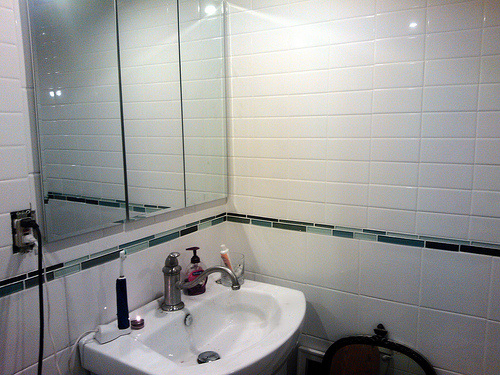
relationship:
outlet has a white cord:
[14, 232, 43, 247] [3, 207, 77, 366]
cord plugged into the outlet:
[3, 207, 77, 366] [14, 232, 43, 247]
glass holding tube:
[24, 81, 314, 216] [216, 244, 236, 283]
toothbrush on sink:
[114, 248, 134, 331] [78, 267, 308, 373]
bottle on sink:
[182, 245, 207, 296] [64, 261, 309, 373]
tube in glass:
[212, 249, 233, 272] [232, 262, 247, 276]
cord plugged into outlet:
[20, 217, 45, 375] [9, 207, 36, 250]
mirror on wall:
[16, 0, 226, 245] [229, 3, 499, 313]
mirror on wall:
[16, 0, 226, 245] [1, 5, 37, 215]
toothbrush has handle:
[114, 248, 134, 331] [114, 276, 129, 328]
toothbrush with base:
[114, 248, 134, 331] [93, 320, 130, 344]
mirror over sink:
[16, 0, 233, 260] [64, 261, 309, 373]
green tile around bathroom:
[374, 230, 430, 247] [1, 1, 483, 371]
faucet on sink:
[160, 244, 255, 302] [76, 246, 309, 373]